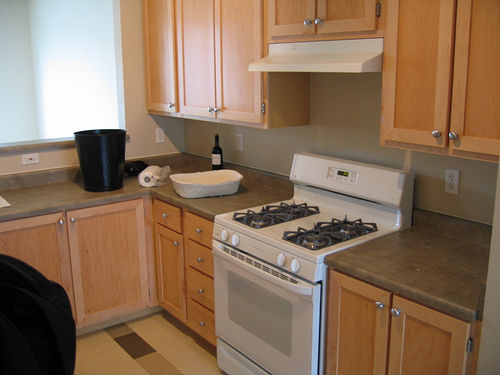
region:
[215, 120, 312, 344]
the gas range is white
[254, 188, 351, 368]
the gas range is white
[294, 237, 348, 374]
the gas range is white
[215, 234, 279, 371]
the gas range is white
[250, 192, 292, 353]
the gas range is white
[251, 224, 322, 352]
the gas range is white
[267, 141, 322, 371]
the gas range is white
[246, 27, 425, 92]
overhead light on stove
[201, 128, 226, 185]
bottle of wine on countertop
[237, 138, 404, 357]
white gas range with led display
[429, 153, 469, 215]
recepticle beside stove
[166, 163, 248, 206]
white containiner on counter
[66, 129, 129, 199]
small black waste basket on counter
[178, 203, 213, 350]
four brown wooden drawers beside stove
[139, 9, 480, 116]
a set of kitchen cabinets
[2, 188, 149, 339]
cabinets under sink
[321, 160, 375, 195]
electronic display ontop of white stove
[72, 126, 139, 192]
black kitchen trash can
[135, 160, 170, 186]
roll of white paper towels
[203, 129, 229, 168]
dark wine bottle on counter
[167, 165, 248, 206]
white casserole dish on counter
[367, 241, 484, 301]
brown granite counter top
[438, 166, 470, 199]
electrical socket in wall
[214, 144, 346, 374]
white stove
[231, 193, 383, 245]
four black burners on top of stove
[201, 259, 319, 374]
white oven door with glass window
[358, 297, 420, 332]
round silver cabinet knobs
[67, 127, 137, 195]
black bucket on top of sink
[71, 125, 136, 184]
black bucket on top of sink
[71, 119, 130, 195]
black bucket on top of sink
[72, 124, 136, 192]
black bucket on top of sink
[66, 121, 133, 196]
black bucket on top of sink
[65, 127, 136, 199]
black bucket on top of sink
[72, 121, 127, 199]
black bucket on top of sink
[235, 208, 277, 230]
Gas stove burner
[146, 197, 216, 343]
Wood kitchen cabinet and drawers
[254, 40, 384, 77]
Under cabinet stove hood vent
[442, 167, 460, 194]
White wall socket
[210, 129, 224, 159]
Top of wine bottle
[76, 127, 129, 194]
Round black bucket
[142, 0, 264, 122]
Kitchen cabinet doors with siver knobs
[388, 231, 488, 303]
Kitchen counter top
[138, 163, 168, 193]
Paper towel roll in plastic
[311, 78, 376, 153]
Beige painted wall